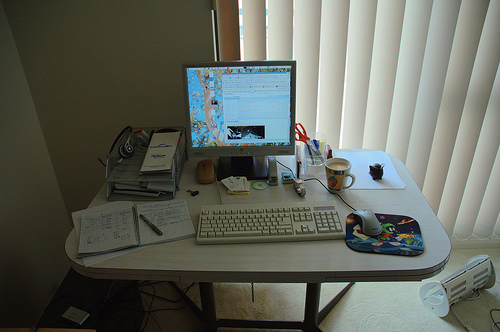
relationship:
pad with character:
[349, 212, 423, 255] [379, 219, 398, 250]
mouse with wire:
[352, 207, 382, 236] [314, 181, 360, 212]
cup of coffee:
[325, 157, 353, 194] [329, 162, 346, 170]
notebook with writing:
[77, 199, 193, 248] [144, 207, 186, 228]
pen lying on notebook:
[141, 212, 164, 237] [77, 199, 193, 248]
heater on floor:
[423, 251, 494, 315] [100, 274, 500, 331]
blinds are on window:
[233, 5, 498, 217] [208, 3, 499, 224]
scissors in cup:
[292, 122, 321, 159] [303, 138, 324, 166]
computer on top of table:
[175, 59, 302, 186] [70, 140, 436, 280]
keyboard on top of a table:
[197, 199, 340, 239] [70, 140, 436, 280]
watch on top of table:
[292, 176, 306, 197] [70, 140, 436, 280]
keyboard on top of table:
[197, 199, 340, 239] [70, 140, 436, 280]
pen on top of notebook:
[141, 212, 164, 237] [77, 199, 193, 248]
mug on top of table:
[325, 157, 353, 194] [70, 140, 436, 280]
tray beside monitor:
[110, 121, 180, 193] [182, 62, 293, 155]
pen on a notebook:
[141, 212, 164, 237] [77, 199, 193, 248]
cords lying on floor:
[67, 281, 195, 329] [100, 274, 500, 331]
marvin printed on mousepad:
[379, 219, 398, 250] [349, 212, 423, 255]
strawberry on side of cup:
[328, 175, 338, 188] [325, 157, 353, 194]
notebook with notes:
[77, 199, 193, 248] [86, 214, 138, 242]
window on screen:
[223, 73, 289, 141] [182, 62, 293, 155]